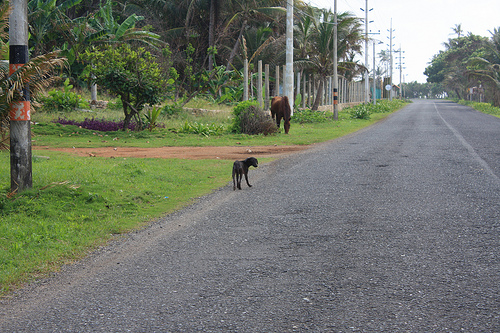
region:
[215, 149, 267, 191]
small dog on the roadside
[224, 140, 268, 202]
black dog in the street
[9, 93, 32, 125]
sign on a metal pole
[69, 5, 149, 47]
palm trees alongside the street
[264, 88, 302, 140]
brown horse grazing on grass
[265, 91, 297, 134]
horse grazing by the street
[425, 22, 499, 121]
trees lining the street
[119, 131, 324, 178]
dirt driveway off the main road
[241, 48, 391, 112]
wooden poles of a fence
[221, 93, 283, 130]
bush by the street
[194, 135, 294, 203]
black dog on road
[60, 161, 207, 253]
green grass near dog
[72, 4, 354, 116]
tropical trees in background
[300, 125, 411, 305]
road is dark grey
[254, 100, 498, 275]
grey road is unlined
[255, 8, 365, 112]
white poles near road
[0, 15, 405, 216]
power poles are tall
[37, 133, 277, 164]
brown dirt road behind dog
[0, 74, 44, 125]
orange sign on pole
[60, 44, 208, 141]
small green trees behind dog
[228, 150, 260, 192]
A small black dog walking along the road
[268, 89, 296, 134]
A large brown horse by the road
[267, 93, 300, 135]
The brown horse is grazing on the green grass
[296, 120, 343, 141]
Short green grass grows by the road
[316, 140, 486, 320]
A black asphalt road by the animals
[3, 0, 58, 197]
A tall, thick pole by the road side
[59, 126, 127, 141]
Dead leaves scattered in the grass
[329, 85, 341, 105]
A yellow and black sign on the metal pole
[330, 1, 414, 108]
A series of telephone poles and wires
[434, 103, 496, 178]
A thin line in the middle of the road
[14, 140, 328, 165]
dirt path leading to the road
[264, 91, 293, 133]
horse grazing near the roadway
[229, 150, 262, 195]
black dog on the road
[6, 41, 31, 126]
black and orang stripes on a pole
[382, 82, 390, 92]
back side of a street sign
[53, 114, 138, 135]
purple flowers under a tree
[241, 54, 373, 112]
wooden poles in a line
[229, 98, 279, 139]
bush near a grazing horse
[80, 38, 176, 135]
tree near purple flowers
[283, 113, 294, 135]
head of a horse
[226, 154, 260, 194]
a dog on the side of the road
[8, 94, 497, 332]
a black paved road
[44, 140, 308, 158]
a brown dirt road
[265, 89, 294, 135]
a brown horse by the side of the road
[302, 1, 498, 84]
a pale gray sky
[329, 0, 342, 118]
a wooden post next to the road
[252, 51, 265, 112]
a wooden fence post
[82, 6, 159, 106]
a green leafed palm tree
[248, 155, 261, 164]
he head of a dog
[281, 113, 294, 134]
the head of a horse